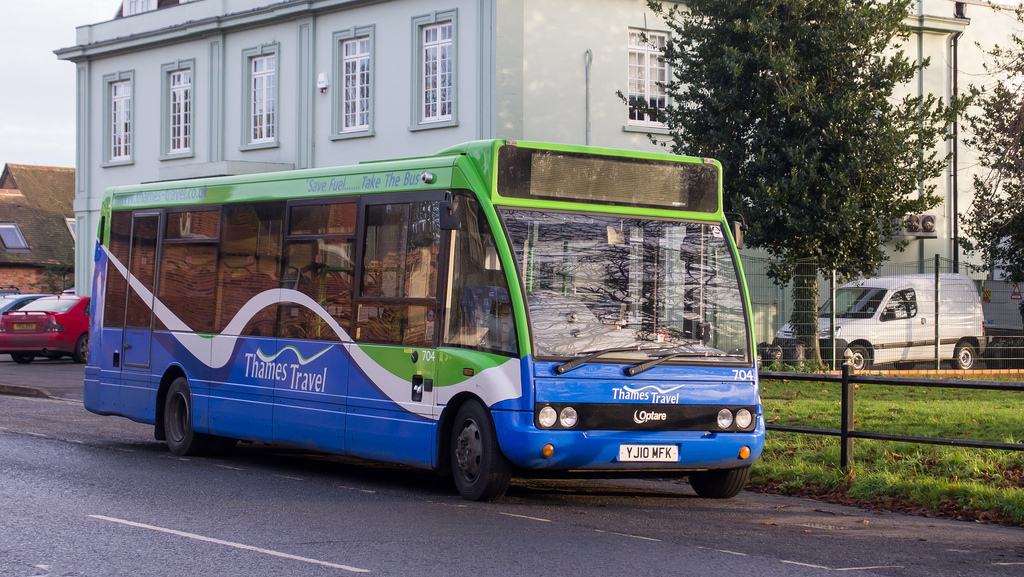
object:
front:
[466, 139, 765, 472]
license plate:
[619, 444, 679, 461]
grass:
[762, 363, 1020, 524]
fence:
[758, 364, 1024, 484]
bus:
[83, 139, 767, 501]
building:
[54, 1, 1024, 369]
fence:
[734, 248, 1022, 370]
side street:
[758, 347, 1021, 370]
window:
[0, 223, 28, 249]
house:
[0, 164, 76, 294]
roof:
[0, 197, 76, 265]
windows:
[106, 189, 520, 360]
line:
[87, 515, 374, 573]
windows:
[99, 9, 458, 168]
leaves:
[614, 18, 1022, 291]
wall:
[72, 0, 652, 185]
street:
[0, 446, 989, 577]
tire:
[451, 399, 512, 501]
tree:
[614, 16, 964, 370]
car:
[770, 273, 1024, 370]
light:
[539, 406, 580, 429]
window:
[342, 35, 370, 134]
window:
[170, 67, 190, 154]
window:
[422, 19, 452, 122]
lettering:
[309, 170, 429, 192]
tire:
[164, 377, 236, 457]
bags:
[758, 319, 813, 368]